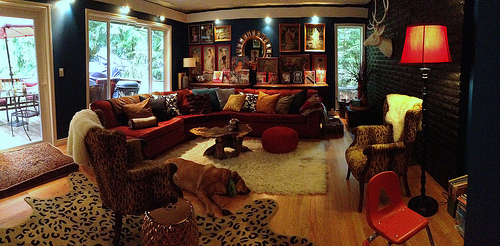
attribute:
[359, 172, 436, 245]
chair — red, small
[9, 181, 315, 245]
rug — leopard skin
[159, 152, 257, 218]
dog — down, brown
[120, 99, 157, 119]
pillow — color, yellow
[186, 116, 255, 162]
table — small, wooden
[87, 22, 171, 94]
window — large, glass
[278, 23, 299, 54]
picture — framed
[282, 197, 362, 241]
floor — wooden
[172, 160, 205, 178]
fur — brown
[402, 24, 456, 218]
lamp — tall, on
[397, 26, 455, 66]
shade — red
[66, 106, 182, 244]
chair — print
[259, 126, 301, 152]
ottoman — red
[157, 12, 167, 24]
light — on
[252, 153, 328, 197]
rug — white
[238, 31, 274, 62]
mirror — round